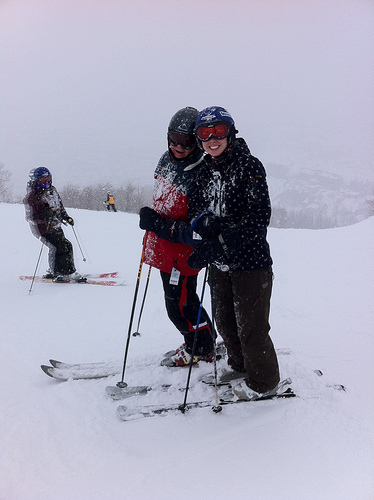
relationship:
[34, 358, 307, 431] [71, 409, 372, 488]
skis on snow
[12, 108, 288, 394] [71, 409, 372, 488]
people in snow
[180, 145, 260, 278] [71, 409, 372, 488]
jacket has snow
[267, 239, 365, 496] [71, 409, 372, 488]
ground has snow